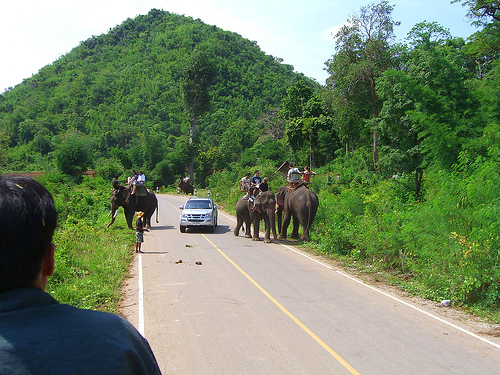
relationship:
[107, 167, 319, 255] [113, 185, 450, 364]
animals on road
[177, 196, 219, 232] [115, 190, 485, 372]
truck driving on road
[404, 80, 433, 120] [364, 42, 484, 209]
green leaves on tree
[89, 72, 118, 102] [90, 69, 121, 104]
leaves on a tree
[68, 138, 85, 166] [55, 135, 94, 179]
leaves on tree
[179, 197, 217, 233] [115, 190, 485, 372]
truck on road